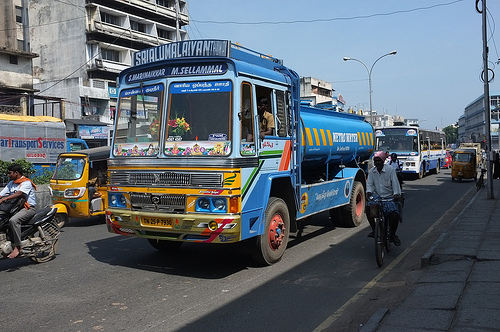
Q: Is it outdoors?
A: Yes, it is outdoors.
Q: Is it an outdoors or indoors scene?
A: It is outdoors.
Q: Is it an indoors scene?
A: No, it is outdoors.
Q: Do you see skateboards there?
A: No, there are no skateboards.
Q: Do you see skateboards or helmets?
A: No, there are no skateboards or helmets.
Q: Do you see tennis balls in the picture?
A: No, there are no tennis balls.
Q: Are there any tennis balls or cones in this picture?
A: No, there are no tennis balls or cones.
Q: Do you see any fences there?
A: No, there are no fences.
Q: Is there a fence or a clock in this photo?
A: No, there are no fences or clocks.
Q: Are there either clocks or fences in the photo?
A: No, there are no fences or clocks.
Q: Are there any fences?
A: No, there are no fences.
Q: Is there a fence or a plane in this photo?
A: No, there are no fences or airplanes.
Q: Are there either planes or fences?
A: No, there are no fences or planes.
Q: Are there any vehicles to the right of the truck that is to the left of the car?
A: No, the vehicle is to the left of the truck.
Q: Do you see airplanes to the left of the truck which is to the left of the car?
A: No, there is a vehicle to the left of the truck.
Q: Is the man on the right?
A: Yes, the man is on the right of the image.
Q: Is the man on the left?
A: No, the man is on the right of the image.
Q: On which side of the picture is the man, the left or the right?
A: The man is on the right of the image.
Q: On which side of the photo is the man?
A: The man is on the right of the image.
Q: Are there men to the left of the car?
A: Yes, there is a man to the left of the car.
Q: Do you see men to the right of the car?
A: No, the man is to the left of the car.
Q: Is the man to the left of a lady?
A: No, the man is to the left of the car.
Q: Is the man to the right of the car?
A: No, the man is to the left of the car.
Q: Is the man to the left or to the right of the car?
A: The man is to the left of the car.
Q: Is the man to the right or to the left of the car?
A: The man is to the left of the car.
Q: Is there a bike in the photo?
A: Yes, there is a bike.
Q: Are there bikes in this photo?
A: Yes, there is a bike.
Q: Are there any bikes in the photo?
A: Yes, there is a bike.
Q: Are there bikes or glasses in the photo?
A: Yes, there is a bike.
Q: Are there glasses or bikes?
A: Yes, there is a bike.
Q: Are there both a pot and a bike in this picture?
A: No, there is a bike but no pots.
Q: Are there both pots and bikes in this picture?
A: No, there is a bike but no pots.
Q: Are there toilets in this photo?
A: No, there are no toilets.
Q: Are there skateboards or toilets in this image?
A: No, there are no toilets or skateboards.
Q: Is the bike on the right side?
A: Yes, the bike is on the right of the image.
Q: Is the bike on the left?
A: No, the bike is on the right of the image.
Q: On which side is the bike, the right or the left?
A: The bike is on the right of the image.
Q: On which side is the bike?
A: The bike is on the right of the image.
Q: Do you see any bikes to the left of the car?
A: Yes, there is a bike to the left of the car.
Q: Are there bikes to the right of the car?
A: No, the bike is to the left of the car.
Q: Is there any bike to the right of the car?
A: No, the bike is to the left of the car.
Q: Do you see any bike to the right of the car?
A: No, the bike is to the left of the car.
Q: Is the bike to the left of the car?
A: Yes, the bike is to the left of the car.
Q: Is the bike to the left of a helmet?
A: No, the bike is to the left of the car.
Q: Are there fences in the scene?
A: No, there are no fences.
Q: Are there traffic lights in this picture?
A: No, there are no traffic lights.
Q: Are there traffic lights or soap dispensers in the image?
A: No, there are no traffic lights or soap dispensers.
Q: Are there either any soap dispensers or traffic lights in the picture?
A: No, there are no traffic lights or soap dispensers.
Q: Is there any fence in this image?
A: No, there are no fences.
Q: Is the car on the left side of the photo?
A: No, the car is on the right of the image.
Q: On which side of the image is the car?
A: The car is on the right of the image.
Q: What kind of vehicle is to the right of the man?
A: The vehicle is a car.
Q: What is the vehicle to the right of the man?
A: The vehicle is a car.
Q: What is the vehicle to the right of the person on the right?
A: The vehicle is a car.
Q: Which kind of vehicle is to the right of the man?
A: The vehicle is a car.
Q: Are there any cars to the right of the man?
A: Yes, there is a car to the right of the man.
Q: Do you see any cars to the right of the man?
A: Yes, there is a car to the right of the man.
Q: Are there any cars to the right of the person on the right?
A: Yes, there is a car to the right of the man.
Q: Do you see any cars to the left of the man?
A: No, the car is to the right of the man.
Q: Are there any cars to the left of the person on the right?
A: No, the car is to the right of the man.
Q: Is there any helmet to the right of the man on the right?
A: No, there is a car to the right of the man.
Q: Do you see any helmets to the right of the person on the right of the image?
A: No, there is a car to the right of the man.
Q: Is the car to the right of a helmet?
A: No, the car is to the right of a man.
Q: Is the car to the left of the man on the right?
A: No, the car is to the right of the man.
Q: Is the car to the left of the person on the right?
A: No, the car is to the right of the man.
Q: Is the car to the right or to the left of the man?
A: The car is to the right of the man.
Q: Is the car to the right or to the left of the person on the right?
A: The car is to the right of the man.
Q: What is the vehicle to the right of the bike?
A: The vehicle is a car.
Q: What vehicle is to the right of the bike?
A: The vehicle is a car.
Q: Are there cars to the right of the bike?
A: Yes, there is a car to the right of the bike.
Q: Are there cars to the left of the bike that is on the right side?
A: No, the car is to the right of the bike.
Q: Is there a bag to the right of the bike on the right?
A: No, there is a car to the right of the bike.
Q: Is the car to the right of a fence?
A: No, the car is to the right of the bike.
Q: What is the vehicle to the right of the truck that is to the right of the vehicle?
A: The vehicle is a car.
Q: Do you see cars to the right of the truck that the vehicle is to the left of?
A: Yes, there is a car to the right of the truck.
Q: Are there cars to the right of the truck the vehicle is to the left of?
A: Yes, there is a car to the right of the truck.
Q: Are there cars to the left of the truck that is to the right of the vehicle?
A: No, the car is to the right of the truck.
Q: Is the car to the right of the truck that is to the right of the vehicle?
A: Yes, the car is to the right of the truck.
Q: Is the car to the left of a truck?
A: No, the car is to the right of a truck.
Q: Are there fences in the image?
A: No, there are no fences.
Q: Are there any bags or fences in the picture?
A: No, there are no fences or bags.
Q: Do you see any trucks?
A: Yes, there is a truck.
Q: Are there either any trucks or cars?
A: Yes, there is a truck.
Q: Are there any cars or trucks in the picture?
A: Yes, there is a truck.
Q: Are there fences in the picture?
A: No, there are no fences.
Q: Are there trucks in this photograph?
A: Yes, there is a truck.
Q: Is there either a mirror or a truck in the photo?
A: Yes, there is a truck.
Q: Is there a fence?
A: No, there are no fences.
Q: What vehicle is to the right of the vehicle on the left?
A: The vehicle is a truck.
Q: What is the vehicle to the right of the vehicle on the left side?
A: The vehicle is a truck.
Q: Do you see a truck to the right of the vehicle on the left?
A: Yes, there is a truck to the right of the vehicle.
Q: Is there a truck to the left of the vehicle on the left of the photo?
A: No, the truck is to the right of the vehicle.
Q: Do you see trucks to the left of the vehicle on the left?
A: No, the truck is to the right of the vehicle.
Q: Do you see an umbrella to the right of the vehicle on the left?
A: No, there is a truck to the right of the vehicle.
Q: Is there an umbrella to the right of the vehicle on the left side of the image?
A: No, there is a truck to the right of the vehicle.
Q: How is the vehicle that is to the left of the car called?
A: The vehicle is a truck.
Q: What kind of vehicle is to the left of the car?
A: The vehicle is a truck.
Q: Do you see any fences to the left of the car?
A: No, there is a truck to the left of the car.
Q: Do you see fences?
A: No, there are no fences.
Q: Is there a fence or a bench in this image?
A: No, there are no fences or benches.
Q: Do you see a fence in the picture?
A: No, there are no fences.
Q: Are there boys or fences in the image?
A: No, there are no fences or boys.